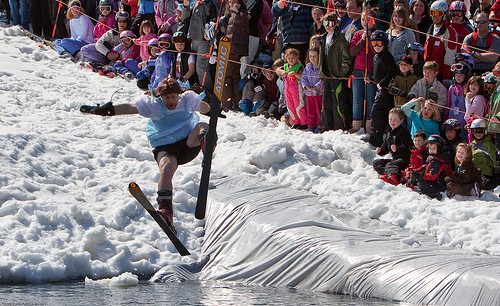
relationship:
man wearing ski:
[79, 79, 217, 226] [128, 182, 189, 256]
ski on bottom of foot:
[123, 186, 188, 257] [156, 196, 180, 219]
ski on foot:
[206, 91, 228, 211] [195, 120, 210, 154]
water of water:
[0, 282, 427, 306] [67, 270, 243, 303]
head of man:
[156, 81, 182, 107] [79, 79, 217, 226]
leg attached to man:
[156, 156, 184, 204] [79, 79, 217, 226]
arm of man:
[70, 92, 142, 114] [79, 79, 217, 226]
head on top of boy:
[385, 107, 407, 131] [370, 109, 406, 162]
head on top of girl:
[263, 43, 305, 64] [253, 38, 291, 123]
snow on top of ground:
[268, 210, 364, 268] [247, 162, 345, 223]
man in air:
[79, 79, 217, 226] [145, 234, 238, 258]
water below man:
[67, 270, 243, 303] [79, 79, 217, 226]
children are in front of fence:
[190, 41, 366, 126] [240, 64, 355, 92]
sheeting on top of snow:
[198, 181, 500, 305] [268, 210, 364, 268]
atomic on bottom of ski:
[213, 42, 238, 106] [123, 186, 188, 257]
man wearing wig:
[79, 79, 217, 226] [154, 80, 179, 93]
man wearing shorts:
[127, 77, 211, 153] [140, 136, 211, 166]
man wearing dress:
[127, 77, 211, 153] [139, 109, 201, 143]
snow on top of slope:
[268, 210, 364, 268] [2, 65, 89, 145]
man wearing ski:
[127, 77, 211, 153] [128, 182, 189, 256]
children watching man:
[190, 41, 366, 126] [79, 79, 217, 226]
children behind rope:
[190, 41, 366, 126] [291, 68, 354, 83]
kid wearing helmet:
[362, 19, 394, 124] [371, 29, 387, 42]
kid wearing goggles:
[362, 19, 394, 124] [368, 39, 382, 47]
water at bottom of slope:
[67, 270, 243, 303] [2, 65, 89, 145]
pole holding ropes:
[359, 10, 368, 130] [274, 9, 438, 102]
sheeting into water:
[175, 271, 281, 287] [67, 270, 243, 303]